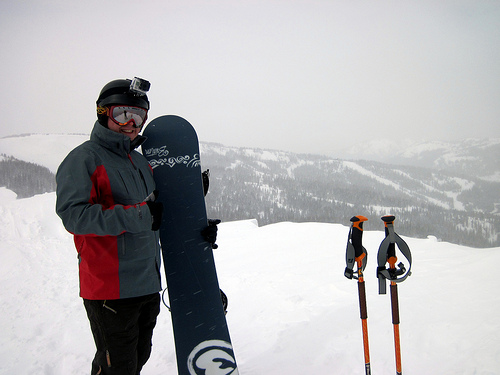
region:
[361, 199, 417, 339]
Ski pole sticking out of ground.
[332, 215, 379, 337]
Ski pole standing out of ground.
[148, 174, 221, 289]
Person holding snowboard in hand.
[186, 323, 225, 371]
White logo on snowboard.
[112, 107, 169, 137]
Goggles on person's face.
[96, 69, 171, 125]
Person wearing black helmet.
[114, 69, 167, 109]
Camera strapped on person's head.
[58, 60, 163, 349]
this is a man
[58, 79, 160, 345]
the man is staring at the camera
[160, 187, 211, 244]
this is a board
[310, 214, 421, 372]
these are two poles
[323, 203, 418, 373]
the poles are thin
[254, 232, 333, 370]
the place is full of snow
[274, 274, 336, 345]
the snow is white in color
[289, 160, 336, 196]
this is a mountain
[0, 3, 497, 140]
light in daytme sky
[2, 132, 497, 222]
hazy mountains with trees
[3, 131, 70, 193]
snow on mountain top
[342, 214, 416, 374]
tops of two poles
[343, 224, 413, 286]
wrist straps on poles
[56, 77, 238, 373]
person posing with snowboard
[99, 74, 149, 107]
camera on black helmet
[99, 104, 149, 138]
goggles on person's face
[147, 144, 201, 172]
white sign on board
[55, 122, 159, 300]
red and gray coat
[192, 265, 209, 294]
part of a boaed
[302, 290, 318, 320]
part of a ground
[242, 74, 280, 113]
part of a cloud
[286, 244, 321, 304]
part of a snioew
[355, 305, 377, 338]
part of a hooker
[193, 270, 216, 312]
aprt of a boaes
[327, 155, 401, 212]
Section of ice on the hill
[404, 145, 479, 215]
Section of ice on the hill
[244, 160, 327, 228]
Section of ice on the hill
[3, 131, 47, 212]
Section of ice on the hill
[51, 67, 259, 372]
This is a person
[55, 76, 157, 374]
a man is posing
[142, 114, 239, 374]
snow board is blue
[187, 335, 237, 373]
the logo is white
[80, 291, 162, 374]
the pants are black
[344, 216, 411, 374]
the poles are orange and gray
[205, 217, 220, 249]
the glove is black